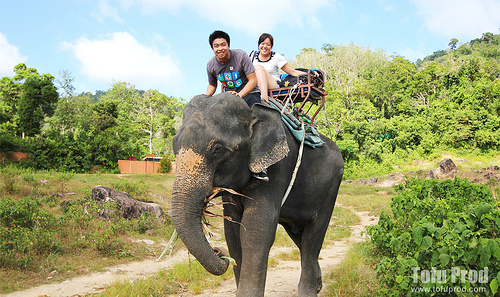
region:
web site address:
[398, 282, 490, 295]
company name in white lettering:
[406, 263, 499, 286]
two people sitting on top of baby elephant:
[158, 21, 343, 294]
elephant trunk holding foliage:
[169, 176, 239, 283]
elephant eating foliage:
[158, 95, 348, 295]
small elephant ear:
[241, 95, 298, 192]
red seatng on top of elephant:
[246, 62, 331, 122]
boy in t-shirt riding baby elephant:
[193, 25, 267, 111]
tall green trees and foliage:
[307, 26, 499, 201]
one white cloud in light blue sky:
[39, 23, 184, 83]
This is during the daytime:
[12, 6, 492, 226]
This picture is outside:
[10, 16, 442, 290]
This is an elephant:
[127, 63, 354, 290]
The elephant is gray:
[174, 99, 330, 276]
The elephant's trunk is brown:
[153, 142, 243, 282]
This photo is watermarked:
[391, 228, 490, 287]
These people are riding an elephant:
[145, 8, 350, 130]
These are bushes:
[360, 179, 471, 293]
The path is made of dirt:
[72, 213, 207, 288]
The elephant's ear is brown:
[224, 125, 295, 179]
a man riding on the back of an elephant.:
[187, 25, 264, 105]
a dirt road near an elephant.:
[1, 177, 378, 291]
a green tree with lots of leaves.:
[13, 90, 134, 167]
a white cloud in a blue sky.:
[54, 23, 189, 95]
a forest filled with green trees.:
[0, 60, 209, 167]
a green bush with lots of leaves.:
[360, 159, 498, 294]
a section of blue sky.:
[364, 23, 407, 42]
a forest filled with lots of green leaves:
[289, 43, 498, 160]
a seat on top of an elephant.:
[258, 56, 335, 108]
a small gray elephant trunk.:
[159, 175, 237, 280]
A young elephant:
[168, 90, 348, 295]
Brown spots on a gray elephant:
[174, 144, 204, 188]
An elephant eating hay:
[168, 176, 248, 276]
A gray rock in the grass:
[86, 180, 168, 227]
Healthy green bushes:
[371, 179, 498, 276]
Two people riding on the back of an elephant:
[173, 32, 338, 295]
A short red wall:
[63, 155, 183, 178]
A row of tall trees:
[318, 54, 488, 171]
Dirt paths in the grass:
[32, 193, 379, 295]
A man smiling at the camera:
[197, 30, 258, 92]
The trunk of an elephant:
[168, 149, 230, 278]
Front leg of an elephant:
[236, 195, 280, 295]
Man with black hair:
[204, 25, 256, 102]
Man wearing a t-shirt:
[203, 27, 255, 102]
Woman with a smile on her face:
[252, 31, 274, 60]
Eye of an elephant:
[207, 135, 227, 162]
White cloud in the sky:
[55, 28, 193, 97]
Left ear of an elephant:
[247, 100, 292, 177]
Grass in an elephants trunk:
[153, 185, 255, 280]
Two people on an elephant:
[167, 20, 349, 295]